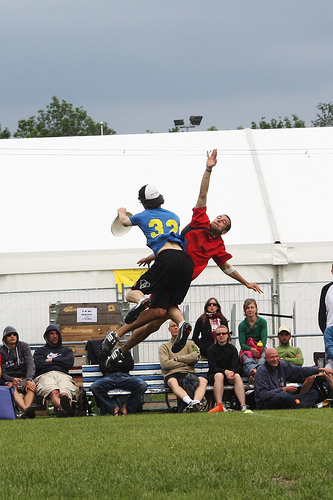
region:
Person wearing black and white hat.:
[136, 183, 161, 203]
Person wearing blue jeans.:
[118, 380, 151, 409]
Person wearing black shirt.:
[108, 361, 130, 370]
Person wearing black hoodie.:
[43, 346, 79, 376]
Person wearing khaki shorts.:
[51, 373, 74, 398]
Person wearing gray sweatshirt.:
[8, 357, 26, 372]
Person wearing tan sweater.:
[167, 349, 192, 373]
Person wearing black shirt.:
[217, 347, 236, 358]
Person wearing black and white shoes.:
[102, 332, 131, 388]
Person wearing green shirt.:
[283, 343, 301, 386]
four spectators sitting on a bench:
[77, 317, 304, 413]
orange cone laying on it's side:
[200, 398, 227, 418]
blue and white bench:
[76, 358, 255, 402]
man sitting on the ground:
[249, 342, 332, 412]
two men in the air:
[86, 145, 272, 364]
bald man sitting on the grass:
[252, 346, 322, 421]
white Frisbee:
[99, 205, 144, 237]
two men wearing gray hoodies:
[2, 315, 76, 417]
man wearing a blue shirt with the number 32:
[140, 214, 184, 238]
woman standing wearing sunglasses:
[195, 295, 229, 366]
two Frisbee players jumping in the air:
[100, 148, 262, 372]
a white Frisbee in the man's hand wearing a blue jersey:
[110, 207, 132, 236]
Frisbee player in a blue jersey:
[110, 183, 190, 353]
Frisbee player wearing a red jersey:
[192, 147, 263, 296]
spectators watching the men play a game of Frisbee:
[1, 263, 332, 419]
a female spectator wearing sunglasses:
[192, 297, 230, 321]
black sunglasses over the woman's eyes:
[205, 300, 218, 307]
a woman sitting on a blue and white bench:
[206, 324, 248, 414]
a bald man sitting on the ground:
[254, 346, 331, 408]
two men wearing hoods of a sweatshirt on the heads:
[1, 324, 82, 417]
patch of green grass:
[83, 429, 185, 472]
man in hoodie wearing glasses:
[2, 322, 22, 350]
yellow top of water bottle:
[254, 337, 264, 351]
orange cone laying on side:
[203, 401, 224, 414]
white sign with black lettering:
[73, 304, 101, 325]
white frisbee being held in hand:
[105, 201, 135, 240]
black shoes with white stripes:
[92, 323, 129, 373]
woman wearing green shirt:
[234, 295, 271, 359]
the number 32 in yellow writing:
[145, 213, 184, 248]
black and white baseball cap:
[134, 178, 167, 211]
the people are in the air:
[60, 178, 262, 349]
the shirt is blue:
[132, 210, 196, 249]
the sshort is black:
[140, 255, 201, 309]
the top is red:
[192, 222, 230, 261]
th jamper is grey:
[0, 344, 38, 382]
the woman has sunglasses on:
[194, 293, 238, 331]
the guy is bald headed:
[256, 349, 320, 409]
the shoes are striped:
[99, 331, 118, 352]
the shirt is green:
[235, 323, 273, 350]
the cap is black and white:
[135, 184, 167, 204]